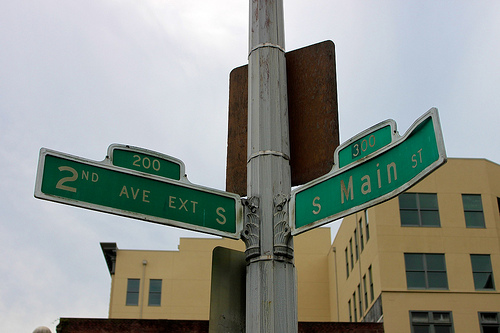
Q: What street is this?
A: South Main Street.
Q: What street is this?
A: 2nd Avenue Ext South.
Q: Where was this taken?
A: A city street.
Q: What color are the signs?
A: Green.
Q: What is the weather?
A: Partly cloudy.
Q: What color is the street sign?
A: The sign is green.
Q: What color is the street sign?
A: The street sign is green.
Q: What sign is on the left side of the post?
A: The sign is for 2nd ave.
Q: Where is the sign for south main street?
A: It is on the right side of the pole.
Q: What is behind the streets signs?
A: There is a tan colored building.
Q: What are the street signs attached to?
A: The signs are connected to a skinny sign pole.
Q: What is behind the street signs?
A: The large yellow building.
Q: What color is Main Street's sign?
A: Green.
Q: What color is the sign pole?
A: Grey.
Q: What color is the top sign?
A: Brown.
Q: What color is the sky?
A: Grey.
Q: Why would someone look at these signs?
A: Directions.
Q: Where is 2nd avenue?
A: To the left.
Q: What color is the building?
A: Yellow.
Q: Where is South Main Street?
A: To the right.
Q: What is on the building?
A: Windows.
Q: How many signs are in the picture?
A: 2.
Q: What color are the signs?
A: Green.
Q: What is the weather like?
A: Cloudy.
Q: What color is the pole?
A: Gray.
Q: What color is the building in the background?
A: Tan.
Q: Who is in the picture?
A: No one.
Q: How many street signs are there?
A: Two.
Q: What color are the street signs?
A: Green and white.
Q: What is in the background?
A: A building.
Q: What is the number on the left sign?
A: 200.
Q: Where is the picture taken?
A: Outside a building.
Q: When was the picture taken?
A: Daytime.